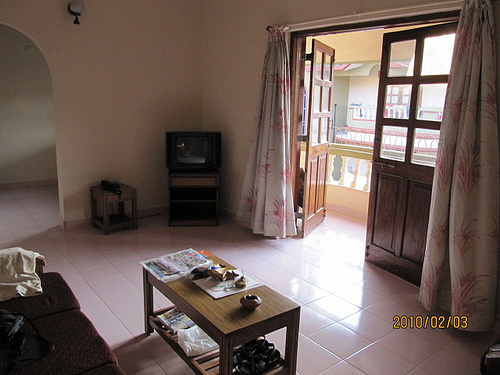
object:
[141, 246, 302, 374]
table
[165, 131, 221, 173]
tv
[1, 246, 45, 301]
cloth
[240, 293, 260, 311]
ashtray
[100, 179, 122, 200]
phone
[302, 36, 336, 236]
door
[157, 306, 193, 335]
newpaper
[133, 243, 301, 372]
shelf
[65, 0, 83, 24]
fixture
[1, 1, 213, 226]
wall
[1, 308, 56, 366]
wires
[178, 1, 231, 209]
corner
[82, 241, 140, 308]
tiles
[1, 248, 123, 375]
sofa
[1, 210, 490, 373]
floor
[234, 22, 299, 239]
curtain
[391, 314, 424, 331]
year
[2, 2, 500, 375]
picture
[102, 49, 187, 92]
part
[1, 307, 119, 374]
section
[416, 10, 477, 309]
patch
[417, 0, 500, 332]
curtains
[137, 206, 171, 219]
cord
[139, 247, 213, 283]
paper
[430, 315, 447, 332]
month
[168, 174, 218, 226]
cupboard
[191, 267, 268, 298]
magazine